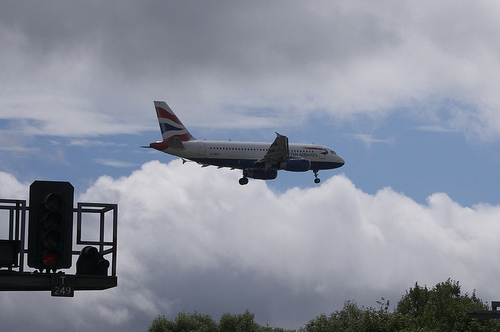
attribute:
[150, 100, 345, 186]
plane — white, blue, red, landing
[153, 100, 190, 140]
tail — colorful, red, blue, white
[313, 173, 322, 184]
wheels — black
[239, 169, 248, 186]
wheels — black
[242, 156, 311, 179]
engines — round, blue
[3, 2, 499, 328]
clouds — white, puffy, plentiful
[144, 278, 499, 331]
trees — tall, green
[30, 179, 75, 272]
light — red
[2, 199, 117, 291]
catwalk — black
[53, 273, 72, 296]
numbers — white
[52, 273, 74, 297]
sign — black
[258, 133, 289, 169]
wing — white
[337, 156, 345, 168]
nose — pointed